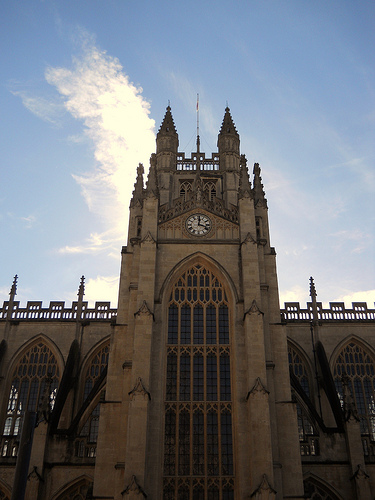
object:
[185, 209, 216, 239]
clock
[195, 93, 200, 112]
flag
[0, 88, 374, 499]
building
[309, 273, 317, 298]
spire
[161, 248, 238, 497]
cathedral window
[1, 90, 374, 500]
front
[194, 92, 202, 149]
spire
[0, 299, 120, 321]
railing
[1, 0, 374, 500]
city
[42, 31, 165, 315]
cloud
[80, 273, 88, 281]
cross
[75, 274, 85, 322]
pole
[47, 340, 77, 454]
railing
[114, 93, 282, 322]
tower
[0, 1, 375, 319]
sky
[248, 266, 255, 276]
spot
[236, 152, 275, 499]
column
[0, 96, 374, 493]
design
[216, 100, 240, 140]
spiral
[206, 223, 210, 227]
roman numerals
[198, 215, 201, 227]
hands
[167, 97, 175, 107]
tip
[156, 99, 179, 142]
spire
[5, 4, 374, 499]
photograph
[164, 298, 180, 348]
windows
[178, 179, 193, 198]
window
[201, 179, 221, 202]
window